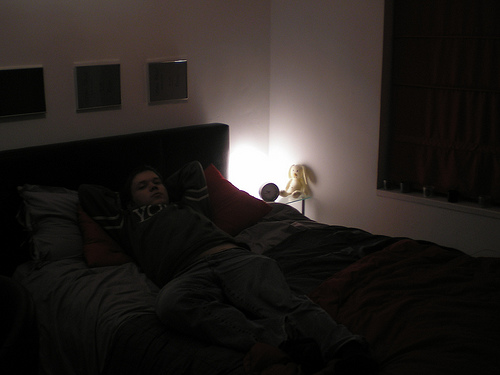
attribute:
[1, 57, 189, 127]
pictures — framed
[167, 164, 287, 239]
pillow — red 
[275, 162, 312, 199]
stuffed rabbit — stuffed 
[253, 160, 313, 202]
light — small 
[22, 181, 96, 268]
pillow — grey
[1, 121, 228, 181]
headboard — wood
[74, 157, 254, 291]
sweater — striped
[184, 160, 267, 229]
pillow — red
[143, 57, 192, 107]
picture — small